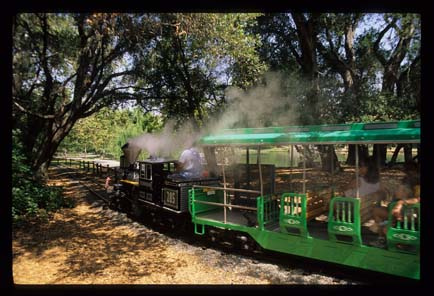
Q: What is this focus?
A: Train tour.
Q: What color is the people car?
A: Green.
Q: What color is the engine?
A: Black.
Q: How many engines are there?
A: 1.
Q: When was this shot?
A: Daytime.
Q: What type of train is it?
A: Kiddie train.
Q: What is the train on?
A: Train tracks.